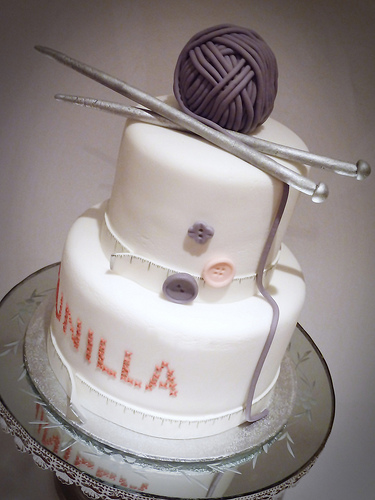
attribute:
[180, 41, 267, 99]
ball — fake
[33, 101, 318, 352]
sculpture — white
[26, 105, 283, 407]
sculpture — white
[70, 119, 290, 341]
sculpture — white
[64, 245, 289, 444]
sculpture — white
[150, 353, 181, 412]
letter — orange 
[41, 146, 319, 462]
sculpure — white 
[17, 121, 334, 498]
sculpure — white 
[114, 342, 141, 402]
letter — orange 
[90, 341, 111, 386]
letter — orange 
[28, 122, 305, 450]
sculpure — white 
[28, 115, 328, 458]
sculpure — white 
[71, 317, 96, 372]
letter — orange 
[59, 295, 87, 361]
letter — orange 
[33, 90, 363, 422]
sculpure — white 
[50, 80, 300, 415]
cake — white 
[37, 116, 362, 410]
cake — white 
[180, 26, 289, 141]
ball — purple 